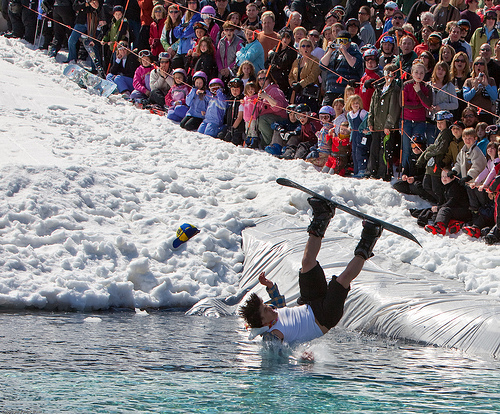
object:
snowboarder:
[238, 176, 423, 349]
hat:
[168, 223, 200, 248]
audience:
[5, 0, 499, 239]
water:
[8, 307, 499, 413]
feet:
[304, 199, 386, 252]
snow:
[4, 145, 135, 314]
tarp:
[186, 219, 499, 360]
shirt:
[272, 302, 322, 342]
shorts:
[296, 262, 352, 329]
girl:
[367, 67, 399, 177]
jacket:
[368, 85, 400, 132]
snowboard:
[275, 176, 425, 248]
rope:
[24, 1, 499, 189]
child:
[163, 68, 225, 139]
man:
[321, 30, 357, 121]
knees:
[179, 113, 217, 140]